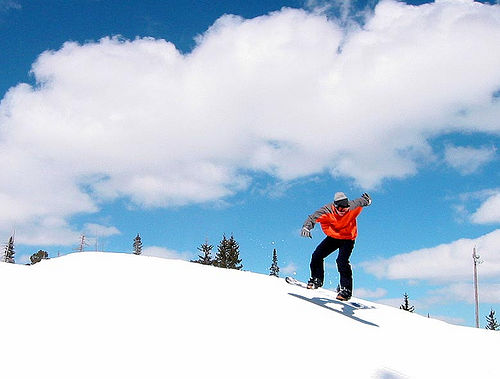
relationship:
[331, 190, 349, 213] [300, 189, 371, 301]
head of man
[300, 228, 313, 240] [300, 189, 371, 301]
hand of man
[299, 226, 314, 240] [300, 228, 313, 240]
glove on hand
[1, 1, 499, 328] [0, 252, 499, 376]
sky over ground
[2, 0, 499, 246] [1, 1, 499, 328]
cloud in sky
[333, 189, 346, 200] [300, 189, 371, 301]
hat on man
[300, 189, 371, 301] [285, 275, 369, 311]
man on snowboard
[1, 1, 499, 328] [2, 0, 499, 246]
sky has cloud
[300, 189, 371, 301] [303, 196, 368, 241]
man has coat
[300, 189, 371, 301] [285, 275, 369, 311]
man has snowboard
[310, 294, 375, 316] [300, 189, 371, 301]
shadow of man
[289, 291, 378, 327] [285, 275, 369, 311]
shadow of snowboard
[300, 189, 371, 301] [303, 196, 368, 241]
man in coat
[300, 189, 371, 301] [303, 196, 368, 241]
man dressed in coat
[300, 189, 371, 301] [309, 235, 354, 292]
man dressed in pants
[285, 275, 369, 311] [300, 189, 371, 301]
snowboard attached to man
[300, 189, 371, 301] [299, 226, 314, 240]
man wearing glove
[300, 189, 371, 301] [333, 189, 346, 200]
man wearing hat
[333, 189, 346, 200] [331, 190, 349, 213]
hat on head